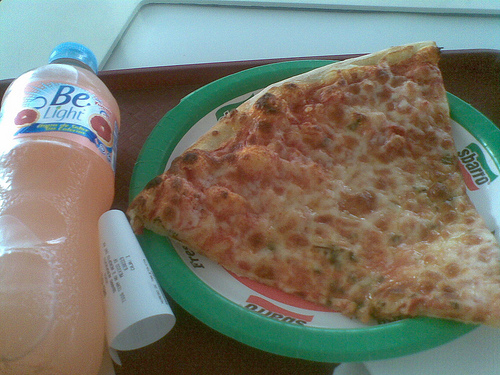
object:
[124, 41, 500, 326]
pizza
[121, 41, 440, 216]
crust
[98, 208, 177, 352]
receipt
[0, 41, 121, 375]
bottle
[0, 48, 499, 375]
tray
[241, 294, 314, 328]
logo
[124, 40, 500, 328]
cheese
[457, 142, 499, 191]
logo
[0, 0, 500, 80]
table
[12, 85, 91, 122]
label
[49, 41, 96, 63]
cap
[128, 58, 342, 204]
rim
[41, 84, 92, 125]
logo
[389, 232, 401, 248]
oregano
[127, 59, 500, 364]
plate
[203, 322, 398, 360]
edge